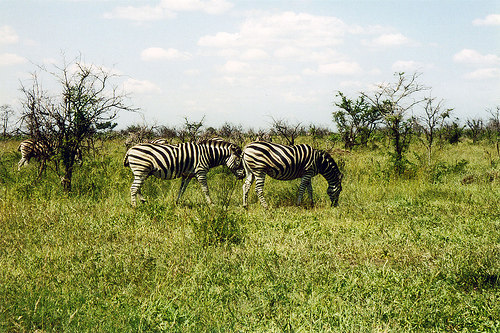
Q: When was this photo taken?
A: During the day.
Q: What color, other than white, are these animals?
A: Black.